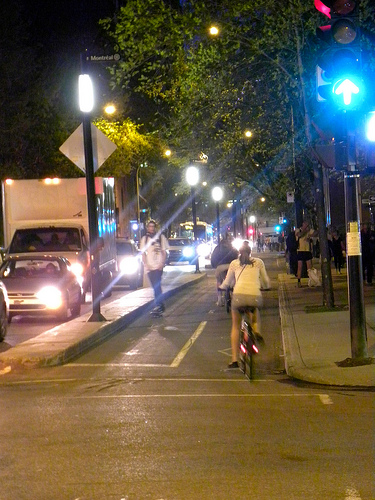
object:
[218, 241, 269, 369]
woman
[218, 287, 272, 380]
bike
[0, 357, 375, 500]
road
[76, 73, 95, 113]
light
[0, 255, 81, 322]
car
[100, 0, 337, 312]
tree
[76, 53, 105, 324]
post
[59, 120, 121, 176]
sign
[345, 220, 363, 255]
paper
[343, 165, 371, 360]
pole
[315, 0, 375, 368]
sign